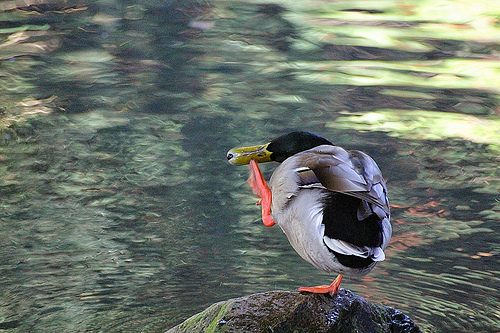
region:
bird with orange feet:
[194, 116, 443, 315]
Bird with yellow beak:
[209, 108, 406, 318]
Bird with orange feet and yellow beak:
[195, 107, 437, 314]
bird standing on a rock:
[136, 114, 461, 331]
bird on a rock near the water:
[134, 86, 399, 331]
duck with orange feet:
[183, 93, 431, 331]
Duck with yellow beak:
[144, 98, 440, 331]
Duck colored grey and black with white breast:
[160, 98, 456, 332]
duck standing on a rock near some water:
[123, 106, 461, 331]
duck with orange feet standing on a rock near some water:
[127, 88, 474, 331]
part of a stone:
[256, 298, 288, 317]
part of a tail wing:
[334, 242, 393, 268]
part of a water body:
[143, 208, 185, 255]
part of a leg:
[249, 171, 269, 220]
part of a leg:
[293, 255, 336, 307]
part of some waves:
[429, 234, 466, 303]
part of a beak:
[222, 140, 247, 171]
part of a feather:
[293, 220, 325, 261]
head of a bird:
[278, 115, 312, 140]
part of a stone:
[280, 307, 303, 323]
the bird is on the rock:
[245, 142, 401, 329]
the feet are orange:
[247, 186, 350, 301]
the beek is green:
[228, 130, 273, 165]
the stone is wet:
[182, 300, 399, 327]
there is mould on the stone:
[185, 286, 408, 331]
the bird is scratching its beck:
[227, 143, 397, 304]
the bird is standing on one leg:
[232, 138, 402, 298]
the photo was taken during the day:
[3, 37, 498, 330]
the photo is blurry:
[4, 36, 496, 329]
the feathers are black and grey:
[260, 146, 417, 283]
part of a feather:
[328, 161, 370, 208]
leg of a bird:
[301, 274, 338, 306]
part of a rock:
[252, 292, 295, 329]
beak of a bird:
[225, 148, 251, 168]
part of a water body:
[126, 165, 182, 223]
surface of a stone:
[255, 301, 295, 328]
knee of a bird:
[252, 207, 276, 232]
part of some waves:
[153, 252, 210, 299]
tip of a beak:
[216, 135, 241, 169]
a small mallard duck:
[218, 117, 413, 307]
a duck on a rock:
[147, 125, 444, 331]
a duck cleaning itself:
[211, 117, 411, 304]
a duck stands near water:
[3, 5, 496, 331]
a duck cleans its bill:
[204, 117, 441, 311]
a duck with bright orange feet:
[155, 113, 426, 327]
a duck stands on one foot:
[151, 115, 445, 331]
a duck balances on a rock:
[153, 102, 448, 331]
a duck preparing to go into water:
[150, 116, 452, 331]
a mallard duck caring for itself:
[153, 122, 463, 331]